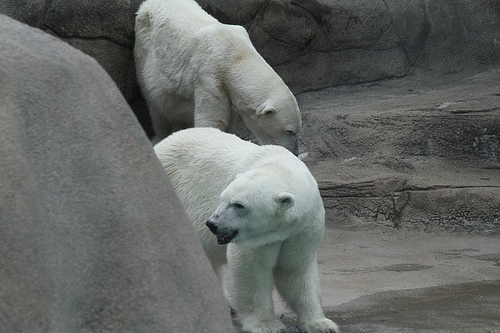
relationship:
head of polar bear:
[250, 89, 307, 162] [127, 2, 311, 161]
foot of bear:
[299, 311, 342, 331] [152, 126, 338, 332]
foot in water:
[299, 311, 342, 331] [339, 294, 492, 331]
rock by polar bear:
[206, 1, 497, 95] [127, 2, 311, 161]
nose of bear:
[201, 215, 220, 233] [152, 126, 338, 332]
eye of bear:
[226, 199, 248, 212] [152, 126, 338, 332]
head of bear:
[203, 166, 278, 254] [152, 126, 338, 332]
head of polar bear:
[250, 89, 302, 155] [127, 2, 311, 161]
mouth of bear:
[207, 217, 244, 246] [152, 126, 338, 332]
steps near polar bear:
[298, 71, 498, 228] [127, 2, 311, 161]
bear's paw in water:
[153, 120, 342, 331] [328, 288, 498, 330]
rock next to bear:
[0, 11, 242, 330] [150, 127, 341, 331]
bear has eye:
[152, 126, 338, 332] [226, 199, 249, 219]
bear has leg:
[152, 126, 338, 332] [277, 211, 335, 331]